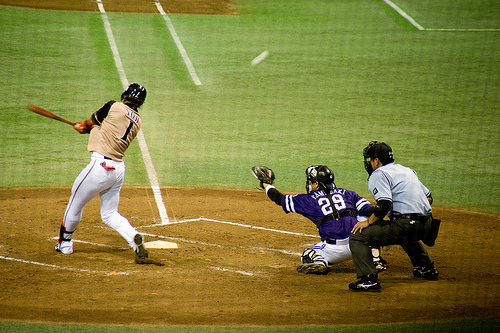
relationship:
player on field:
[69, 65, 152, 268] [58, 16, 464, 157]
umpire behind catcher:
[357, 139, 450, 254] [248, 163, 391, 274]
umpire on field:
[357, 139, 450, 254] [58, 16, 464, 157]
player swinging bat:
[69, 65, 152, 268] [32, 92, 77, 148]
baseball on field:
[248, 41, 271, 77] [58, 16, 464, 157]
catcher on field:
[248, 163, 391, 274] [58, 16, 464, 157]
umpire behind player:
[357, 139, 450, 254] [69, 65, 152, 268]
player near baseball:
[69, 65, 152, 268] [248, 41, 271, 77]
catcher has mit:
[259, 144, 353, 255] [238, 151, 273, 190]